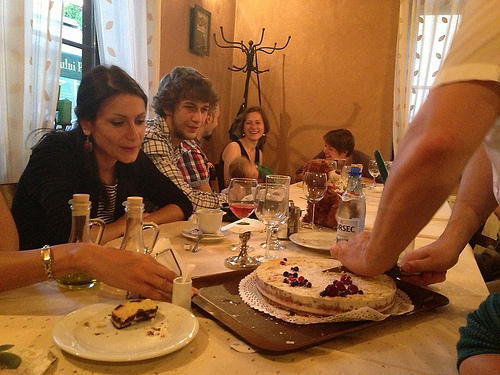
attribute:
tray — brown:
[191, 270, 450, 352]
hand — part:
[2, 243, 198, 300]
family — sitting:
[1, 67, 385, 304]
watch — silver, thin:
[42, 244, 55, 280]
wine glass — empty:
[257, 183, 287, 262]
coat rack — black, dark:
[213, 27, 291, 142]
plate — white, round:
[52, 304, 198, 362]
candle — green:
[57, 100, 71, 127]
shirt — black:
[12, 127, 193, 251]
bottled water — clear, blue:
[338, 168, 365, 241]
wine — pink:
[229, 203, 256, 220]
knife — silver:
[323, 266, 421, 276]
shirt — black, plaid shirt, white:
[141, 118, 228, 210]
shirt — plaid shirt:
[176, 138, 210, 185]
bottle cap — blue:
[349, 166, 362, 178]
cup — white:
[189, 209, 222, 235]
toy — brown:
[303, 159, 342, 228]